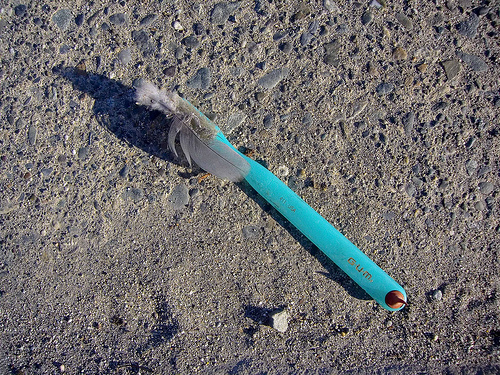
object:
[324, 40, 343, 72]
surface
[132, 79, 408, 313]
toothbrush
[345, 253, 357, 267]
lettering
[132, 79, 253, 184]
feather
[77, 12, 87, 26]
pebble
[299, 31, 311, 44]
rocks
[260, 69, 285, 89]
spot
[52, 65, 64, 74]
sand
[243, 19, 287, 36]
dirt